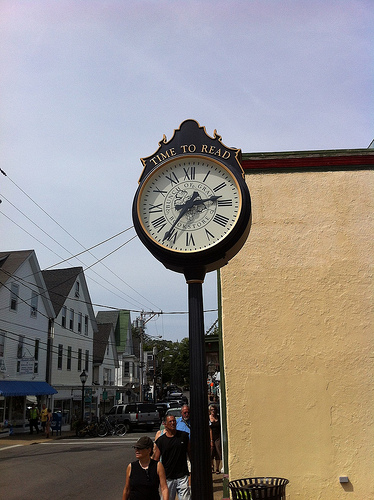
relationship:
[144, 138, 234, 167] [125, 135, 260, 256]
wording on clock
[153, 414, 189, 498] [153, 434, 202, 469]
man wearing sleeveless black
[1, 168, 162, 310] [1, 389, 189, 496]
powerline hanging over street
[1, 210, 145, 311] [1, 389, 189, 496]
powerline hanging over street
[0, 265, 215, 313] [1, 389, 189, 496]
powerline hanging over street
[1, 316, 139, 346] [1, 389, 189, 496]
powerline hanging over street